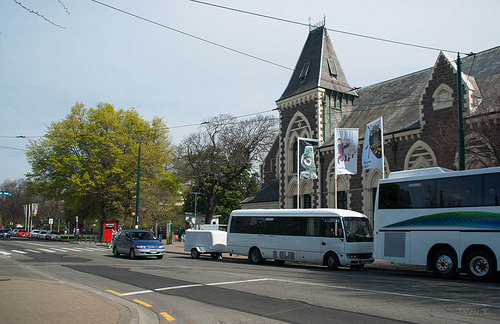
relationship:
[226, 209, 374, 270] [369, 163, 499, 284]
bus behind bus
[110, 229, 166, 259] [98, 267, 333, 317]
car driving on road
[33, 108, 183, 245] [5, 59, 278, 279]
green tree in distance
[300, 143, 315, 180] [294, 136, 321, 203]
poster hanging from pole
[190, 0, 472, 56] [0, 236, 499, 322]
phone wires above ground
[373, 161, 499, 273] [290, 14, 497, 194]
bus in front of church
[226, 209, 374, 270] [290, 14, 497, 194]
bus in front of church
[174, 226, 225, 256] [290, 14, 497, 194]
trailer in front of church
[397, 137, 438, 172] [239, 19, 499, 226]
arch on facade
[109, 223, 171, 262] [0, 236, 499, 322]
car driving on ground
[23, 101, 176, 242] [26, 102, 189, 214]
green tree with leaves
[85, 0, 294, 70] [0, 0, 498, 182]
phone wires crossing sky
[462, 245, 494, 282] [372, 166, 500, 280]
black wheel on bus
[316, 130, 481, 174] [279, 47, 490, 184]
banners in front of church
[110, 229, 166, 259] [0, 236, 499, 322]
car on ground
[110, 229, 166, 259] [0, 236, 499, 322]
car are on ground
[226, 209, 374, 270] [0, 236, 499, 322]
bus are on ground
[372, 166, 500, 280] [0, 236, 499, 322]
bus are on ground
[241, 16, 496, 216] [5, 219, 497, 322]
building by road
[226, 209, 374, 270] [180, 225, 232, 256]
bus pulling trailer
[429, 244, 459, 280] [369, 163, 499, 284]
black wheel on bus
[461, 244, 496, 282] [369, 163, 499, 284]
black wheel on bus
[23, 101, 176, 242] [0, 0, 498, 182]
green tree in sky